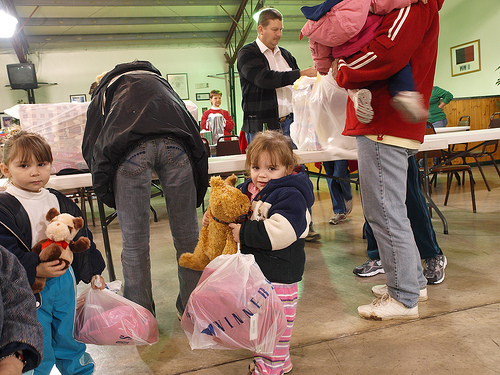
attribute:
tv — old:
[5, 61, 38, 85]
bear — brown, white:
[30, 206, 91, 293]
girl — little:
[0, 126, 107, 373]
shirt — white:
[201, 107, 232, 152]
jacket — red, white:
[348, 1, 426, 133]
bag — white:
[179, 253, 282, 360]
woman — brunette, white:
[197, 90, 239, 147]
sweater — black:
[241, 38, 298, 121]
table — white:
[22, 115, 498, 288]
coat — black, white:
[236, 169, 314, 278]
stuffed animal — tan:
[30, 207, 92, 370]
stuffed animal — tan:
[183, 174, 237, 268]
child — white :
[151, 117, 341, 296]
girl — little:
[174, 128, 323, 370]